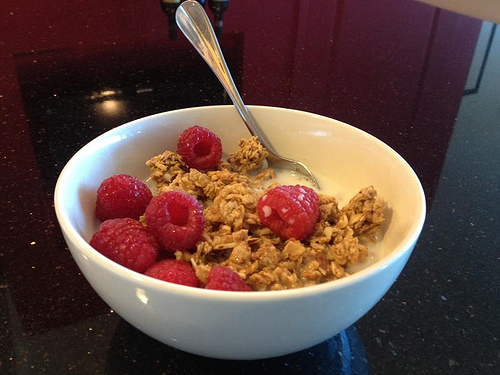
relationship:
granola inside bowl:
[146, 138, 382, 290] [53, 105, 428, 360]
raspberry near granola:
[257, 186, 318, 240] [146, 138, 382, 290]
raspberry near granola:
[177, 126, 222, 170] [146, 138, 382, 290]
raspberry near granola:
[145, 192, 204, 250] [146, 138, 382, 290]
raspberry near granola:
[95, 175, 153, 220] [146, 138, 382, 290]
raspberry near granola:
[90, 218, 158, 272] [146, 138, 382, 290]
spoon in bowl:
[175, 0, 320, 192] [53, 105, 428, 360]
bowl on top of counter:
[53, 105, 428, 360] [1, 2, 499, 374]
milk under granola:
[133, 158, 383, 299] [146, 138, 382, 290]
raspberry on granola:
[177, 126, 222, 170] [146, 138, 382, 290]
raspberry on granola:
[257, 186, 318, 240] [146, 138, 382, 290]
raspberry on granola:
[95, 175, 153, 220] [146, 138, 382, 290]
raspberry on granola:
[145, 192, 204, 250] [146, 138, 382, 290]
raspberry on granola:
[90, 218, 158, 272] [146, 138, 382, 290]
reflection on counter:
[11, 32, 243, 219] [1, 2, 499, 374]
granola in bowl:
[146, 138, 382, 290] [53, 105, 428, 360]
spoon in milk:
[175, 0, 320, 192] [133, 158, 383, 299]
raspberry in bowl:
[177, 126, 222, 170] [53, 105, 428, 360]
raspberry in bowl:
[257, 186, 318, 240] [53, 105, 428, 360]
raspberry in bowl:
[95, 175, 153, 220] [53, 105, 428, 360]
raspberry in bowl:
[145, 192, 204, 250] [53, 105, 428, 360]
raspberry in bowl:
[90, 218, 158, 272] [53, 105, 428, 360]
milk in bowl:
[133, 158, 383, 299] [53, 105, 428, 360]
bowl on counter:
[53, 105, 428, 360] [1, 2, 499, 374]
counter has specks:
[1, 2, 499, 374] [111, 41, 114, 43]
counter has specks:
[1, 2, 499, 374] [53, 93, 58, 96]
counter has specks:
[1, 2, 499, 374] [29, 49, 36, 62]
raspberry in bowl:
[205, 266, 247, 294] [53, 105, 428, 360]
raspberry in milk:
[257, 186, 318, 240] [133, 158, 383, 299]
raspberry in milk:
[177, 126, 222, 170] [133, 158, 383, 299]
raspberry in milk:
[145, 192, 204, 250] [133, 158, 383, 299]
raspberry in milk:
[95, 175, 153, 220] [133, 158, 383, 299]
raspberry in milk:
[205, 266, 247, 294] [133, 158, 383, 299]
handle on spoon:
[174, 2, 272, 152] [175, 0, 320, 192]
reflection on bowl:
[53, 134, 120, 232] [53, 105, 428, 360]